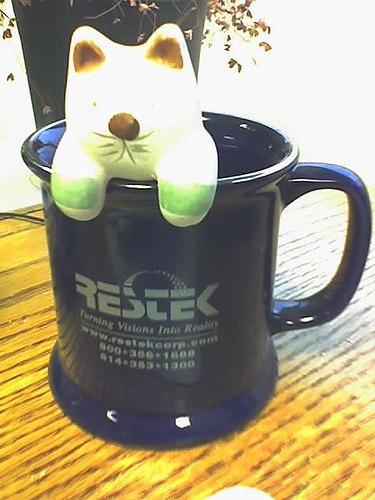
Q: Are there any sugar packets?
A: No, there are no sugar packets.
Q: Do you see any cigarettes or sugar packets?
A: No, there are no sugar packets or cigarettes.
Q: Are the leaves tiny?
A: Yes, the leaves are tiny.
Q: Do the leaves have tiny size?
A: Yes, the leaves are tiny.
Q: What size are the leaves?
A: The leaves are tiny.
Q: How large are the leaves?
A: The leaves are tiny.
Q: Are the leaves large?
A: No, the leaves are tiny.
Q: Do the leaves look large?
A: No, the leaves are tiny.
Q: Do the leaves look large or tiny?
A: The leaves are tiny.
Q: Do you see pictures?
A: No, there are no pictures.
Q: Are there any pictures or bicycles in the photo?
A: No, there are no pictures or bicycles.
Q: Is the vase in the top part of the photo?
A: Yes, the vase is in the top of the image.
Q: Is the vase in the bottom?
A: No, the vase is in the top of the image.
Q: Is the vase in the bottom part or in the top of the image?
A: The vase is in the top of the image.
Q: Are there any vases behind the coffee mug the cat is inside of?
A: Yes, there is a vase behind the coffee mug.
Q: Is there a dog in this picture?
A: No, there are no dogs.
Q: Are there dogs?
A: No, there are no dogs.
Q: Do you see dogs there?
A: No, there are no dogs.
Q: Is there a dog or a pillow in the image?
A: No, there are no dogs or pillows.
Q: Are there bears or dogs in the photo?
A: No, there are no dogs or bears.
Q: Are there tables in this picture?
A: Yes, there is a table.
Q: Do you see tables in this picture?
A: Yes, there is a table.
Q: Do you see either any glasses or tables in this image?
A: Yes, there is a table.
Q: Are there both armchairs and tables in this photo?
A: No, there is a table but no armchairs.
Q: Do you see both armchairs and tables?
A: No, there is a table but no armchairs.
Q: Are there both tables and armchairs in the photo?
A: No, there is a table but no armchairs.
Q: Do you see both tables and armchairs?
A: No, there is a table but no armchairs.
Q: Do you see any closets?
A: No, there are no closets.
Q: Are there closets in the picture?
A: No, there are no closets.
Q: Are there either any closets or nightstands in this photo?
A: No, there are no closets or nightstands.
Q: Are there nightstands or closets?
A: No, there are no closets or nightstands.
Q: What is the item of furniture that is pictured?
A: The piece of furniture is a table.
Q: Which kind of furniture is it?
A: The piece of furniture is a table.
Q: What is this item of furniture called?
A: This is a table.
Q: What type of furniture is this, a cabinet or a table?
A: This is a table.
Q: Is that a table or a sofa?
A: That is a table.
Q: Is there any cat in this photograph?
A: Yes, there is a cat.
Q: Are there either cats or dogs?
A: Yes, there is a cat.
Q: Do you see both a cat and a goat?
A: No, there is a cat but no goats.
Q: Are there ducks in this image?
A: No, there are no ducks.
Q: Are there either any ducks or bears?
A: No, there are no ducks or bears.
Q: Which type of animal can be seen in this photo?
A: The animal is a cat.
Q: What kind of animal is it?
A: The animal is a cat.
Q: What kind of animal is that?
A: This is a cat.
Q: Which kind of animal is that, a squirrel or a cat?
A: This is a cat.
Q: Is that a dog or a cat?
A: That is a cat.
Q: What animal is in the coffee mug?
A: The cat is in the coffee mug.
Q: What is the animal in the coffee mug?
A: The animal is a cat.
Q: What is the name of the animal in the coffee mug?
A: The animal is a cat.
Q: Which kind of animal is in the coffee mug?
A: The animal is a cat.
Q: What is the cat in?
A: The cat is in the coffee mug.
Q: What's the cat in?
A: The cat is in the coffee mug.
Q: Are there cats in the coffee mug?
A: Yes, there is a cat in the coffee mug.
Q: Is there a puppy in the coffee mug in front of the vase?
A: No, there is a cat in the coffee mug.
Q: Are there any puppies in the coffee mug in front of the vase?
A: No, there is a cat in the coffee mug.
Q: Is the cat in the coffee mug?
A: Yes, the cat is in the coffee mug.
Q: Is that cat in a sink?
A: No, the cat is in the coffee mug.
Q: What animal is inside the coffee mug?
A: The cat is inside the coffee mug.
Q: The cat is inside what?
A: The cat is inside the coffee mug.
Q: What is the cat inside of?
A: The cat is inside the coffee mug.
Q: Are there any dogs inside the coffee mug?
A: No, there is a cat inside the coffee mug.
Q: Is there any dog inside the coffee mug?
A: No, there is a cat inside the coffee mug.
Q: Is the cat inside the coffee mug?
A: Yes, the cat is inside the coffee mug.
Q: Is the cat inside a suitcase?
A: No, the cat is inside the coffee mug.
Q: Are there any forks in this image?
A: No, there are no forks.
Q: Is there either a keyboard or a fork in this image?
A: No, there are no forks or keyboards.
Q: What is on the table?
A: The coffee mug is on the table.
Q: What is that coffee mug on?
A: The coffee mug is on the table.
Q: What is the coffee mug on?
A: The coffee mug is on the table.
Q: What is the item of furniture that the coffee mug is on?
A: The piece of furniture is a table.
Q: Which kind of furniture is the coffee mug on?
A: The coffee mug is on the table.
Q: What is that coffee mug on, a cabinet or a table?
A: The coffee mug is on a table.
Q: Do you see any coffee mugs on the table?
A: Yes, there is a coffee mug on the table.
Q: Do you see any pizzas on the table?
A: No, there is a coffee mug on the table.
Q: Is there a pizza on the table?
A: No, there is a coffee mug on the table.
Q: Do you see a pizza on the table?
A: No, there is a coffee mug on the table.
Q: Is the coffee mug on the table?
A: Yes, the coffee mug is on the table.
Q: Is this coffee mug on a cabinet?
A: No, the coffee mug is on the table.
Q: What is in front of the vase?
A: The coffee mug is in front of the vase.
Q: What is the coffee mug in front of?
A: The coffee mug is in front of the vase.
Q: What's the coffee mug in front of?
A: The coffee mug is in front of the vase.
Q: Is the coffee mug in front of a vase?
A: Yes, the coffee mug is in front of a vase.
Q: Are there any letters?
A: Yes, there are letters.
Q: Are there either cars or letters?
A: Yes, there are letters.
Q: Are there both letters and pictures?
A: No, there are letters but no pictures.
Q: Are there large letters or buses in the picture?
A: Yes, there are large letters.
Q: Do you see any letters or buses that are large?
A: Yes, the letters are large.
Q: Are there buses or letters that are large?
A: Yes, the letters are large.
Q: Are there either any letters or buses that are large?
A: Yes, the letters are large.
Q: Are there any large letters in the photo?
A: Yes, there are large letters.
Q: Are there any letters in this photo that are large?
A: Yes, there are letters that are large.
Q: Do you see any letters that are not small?
A: Yes, there are large letters.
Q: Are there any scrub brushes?
A: No, there are no scrub brushes.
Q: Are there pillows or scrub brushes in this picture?
A: No, there are no scrub brushes or pillows.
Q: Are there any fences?
A: No, there are no fences.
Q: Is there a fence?
A: No, there are no fences.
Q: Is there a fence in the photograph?
A: No, there are no fences.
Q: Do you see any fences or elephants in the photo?
A: No, there are no fences or elephants.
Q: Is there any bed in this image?
A: No, there are no beds.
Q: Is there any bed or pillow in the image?
A: No, there are no beds or pillows.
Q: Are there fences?
A: No, there are no fences.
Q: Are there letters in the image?
A: Yes, there are letters.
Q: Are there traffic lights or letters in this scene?
A: Yes, there are letters.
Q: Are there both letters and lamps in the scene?
A: No, there are letters but no lamps.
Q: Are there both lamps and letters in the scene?
A: No, there are letters but no lamps.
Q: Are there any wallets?
A: No, there are no wallets.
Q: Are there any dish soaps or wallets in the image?
A: No, there are no wallets or dish soaps.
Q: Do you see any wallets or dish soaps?
A: No, there are no wallets or dish soaps.